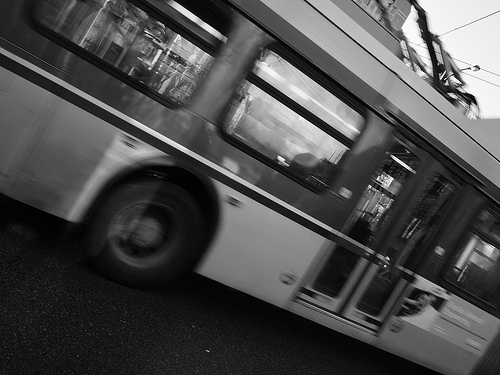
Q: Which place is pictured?
A: It is a street.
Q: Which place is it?
A: It is a street.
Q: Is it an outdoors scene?
A: Yes, it is outdoors.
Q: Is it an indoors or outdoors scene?
A: It is outdoors.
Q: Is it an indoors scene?
A: No, it is outdoors.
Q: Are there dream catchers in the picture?
A: No, there are no dream catchers.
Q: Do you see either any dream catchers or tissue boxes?
A: No, there are no dream catchers or tissue boxes.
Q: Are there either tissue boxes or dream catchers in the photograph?
A: No, there are no dream catchers or tissue boxes.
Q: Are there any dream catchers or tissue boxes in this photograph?
A: No, there are no dream catchers or tissue boxes.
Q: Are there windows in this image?
A: Yes, there is a window.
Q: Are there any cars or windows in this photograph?
A: Yes, there is a window.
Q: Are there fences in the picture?
A: No, there are no fences.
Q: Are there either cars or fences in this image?
A: No, there are no fences or cars.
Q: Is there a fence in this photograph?
A: No, there are no fences.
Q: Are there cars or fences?
A: No, there are no fences or cars.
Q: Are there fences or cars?
A: No, there are no fences or cars.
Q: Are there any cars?
A: No, there are no cars.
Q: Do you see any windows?
A: Yes, there is a window.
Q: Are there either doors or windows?
A: Yes, there is a window.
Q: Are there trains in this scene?
A: No, there are no trains.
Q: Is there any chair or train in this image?
A: No, there are no trains or chairs.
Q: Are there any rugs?
A: No, there are no rugs.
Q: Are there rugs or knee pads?
A: No, there are no rugs or knee pads.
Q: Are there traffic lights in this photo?
A: No, there are no traffic lights.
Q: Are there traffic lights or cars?
A: No, there are no traffic lights or cars.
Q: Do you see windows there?
A: Yes, there is a window.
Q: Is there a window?
A: Yes, there is a window.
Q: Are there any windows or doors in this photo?
A: Yes, there is a window.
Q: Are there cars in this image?
A: No, there are no cars.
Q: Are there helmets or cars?
A: No, there are no cars or helmets.